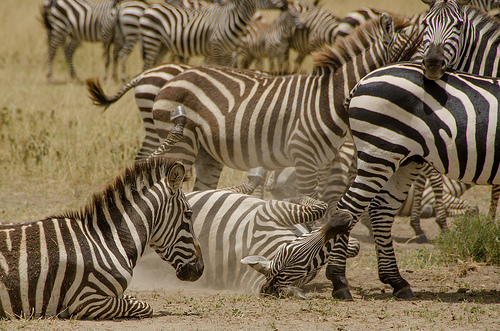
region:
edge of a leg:
[317, 224, 336, 250]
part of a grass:
[442, 238, 464, 266]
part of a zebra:
[316, 222, 322, 229]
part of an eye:
[185, 211, 197, 233]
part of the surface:
[185, 293, 204, 315]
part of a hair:
[141, 159, 147, 174]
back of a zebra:
[213, 239, 223, 264]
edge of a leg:
[401, 196, 422, 232]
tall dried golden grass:
[3, 84, 133, 188]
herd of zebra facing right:
[1, 2, 498, 318]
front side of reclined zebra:
[2, 158, 204, 320]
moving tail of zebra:
[86, 75, 135, 108]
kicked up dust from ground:
[132, 248, 499, 328]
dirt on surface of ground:
[8, 215, 497, 329]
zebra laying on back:
[138, 103, 360, 294]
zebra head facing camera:
[416, 1, 467, 79]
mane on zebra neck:
[318, 20, 383, 70]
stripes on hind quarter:
[350, 64, 494, 183]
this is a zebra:
[0, 144, 252, 319]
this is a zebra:
[192, 186, 349, 293]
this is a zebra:
[164, 26, 404, 197]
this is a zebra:
[142, 7, 266, 77]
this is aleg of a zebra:
[328, 156, 394, 299]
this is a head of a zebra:
[95, 153, 216, 283]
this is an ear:
[157, 160, 187, 200]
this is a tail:
[72, 70, 147, 113]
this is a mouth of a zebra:
[413, 32, 464, 92]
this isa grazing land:
[6, 5, 490, 330]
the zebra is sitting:
[17, 158, 224, 329]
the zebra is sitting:
[14, 151, 209, 327]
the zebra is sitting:
[39, 156, 214, 318]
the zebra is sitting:
[37, 145, 232, 324]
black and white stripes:
[349, 75, 499, 187]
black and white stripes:
[352, 81, 497, 178]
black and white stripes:
[347, 81, 499, 177]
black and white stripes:
[354, 86, 468, 166]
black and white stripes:
[345, 75, 460, 154]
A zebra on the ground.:
[1, 158, 206, 322]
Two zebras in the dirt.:
[3, 153, 361, 321]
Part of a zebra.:
[323, 62, 498, 303]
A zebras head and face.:
[419, 0, 469, 81]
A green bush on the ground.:
[412, 202, 499, 272]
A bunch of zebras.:
[1, 1, 498, 321]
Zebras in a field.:
[1, 1, 499, 329]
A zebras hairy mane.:
[43, 153, 172, 219]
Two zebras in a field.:
[151, 3, 499, 210]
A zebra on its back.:
[143, 103, 360, 302]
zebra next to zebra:
[1, 153, 204, 319]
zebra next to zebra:
[133, 184, 361, 297]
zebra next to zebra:
[325, 61, 497, 299]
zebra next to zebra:
[35, 0, 120, 85]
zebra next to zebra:
[97, 0, 150, 84]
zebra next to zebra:
[140, 0, 253, 70]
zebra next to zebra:
[231, 5, 309, 77]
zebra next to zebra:
[286, 4, 337, 79]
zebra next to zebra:
[333, 5, 390, 39]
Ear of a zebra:
[163, 159, 185, 196]